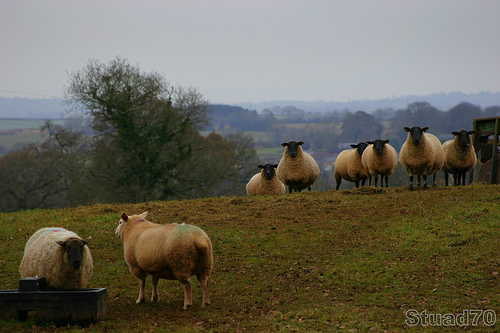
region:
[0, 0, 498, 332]
an outdoor scene of a herd of sheep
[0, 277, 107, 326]
a water trough for the sheep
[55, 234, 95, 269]
the black face of the sheep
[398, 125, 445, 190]
thick wool of the sheep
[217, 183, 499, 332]
a hilly field for sheep grazing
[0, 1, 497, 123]
grey hazy sky in the distance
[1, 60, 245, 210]
large trees on the other side of the hill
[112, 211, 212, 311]
this sheep has a white face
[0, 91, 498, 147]
hills and valleys in the distance behind the sheep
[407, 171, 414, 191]
skinny legs of the sheep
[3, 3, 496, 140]
The sky is grey.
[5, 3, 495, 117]
The sky is overcast.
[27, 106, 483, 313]
Sheep are grazing.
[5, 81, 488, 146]
Mountains in the background.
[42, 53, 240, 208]
The leaves are green.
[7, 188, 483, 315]
The grass is brown and green.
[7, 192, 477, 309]
The grass is patchy.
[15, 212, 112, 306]
Sheep laying down.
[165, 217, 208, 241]
Green marking on sheep.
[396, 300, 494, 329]
The text is white.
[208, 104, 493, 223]
sheep standing on a hill top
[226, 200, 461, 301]
ground is brown and green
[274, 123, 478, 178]
sheep have black faces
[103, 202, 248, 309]
sheep not facing camera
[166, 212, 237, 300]
sheep with green marking on back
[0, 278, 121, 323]
container of water for sheep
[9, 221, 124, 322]
sheep by water container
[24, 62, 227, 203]
nearby tree tops are visible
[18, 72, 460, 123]
lots of hills in the background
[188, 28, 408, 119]
sky is grey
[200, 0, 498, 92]
sky with white clouds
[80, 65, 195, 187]
a tree with green leaves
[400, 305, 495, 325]
Name of the photographer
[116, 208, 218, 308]
a white sheep in field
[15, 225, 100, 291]
a sheep covered in white wool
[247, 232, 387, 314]
a field with green grass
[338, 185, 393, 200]
a mound of green grass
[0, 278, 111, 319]
a sheep feeding bin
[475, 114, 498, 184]
a brown wooden sign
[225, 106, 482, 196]
a group of sheep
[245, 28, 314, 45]
hazy sky in the background.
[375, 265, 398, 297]
grass on the ground.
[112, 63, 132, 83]
bare branches on the trees.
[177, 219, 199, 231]
green patch on sheep's back.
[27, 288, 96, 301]
trough for the sheep.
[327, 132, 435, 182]
group of sheep on the hill.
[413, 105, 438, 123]
trees in the distance.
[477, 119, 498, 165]
wooden fence near the sheep.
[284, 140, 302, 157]
black head of sheep.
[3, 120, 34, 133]
pasture in the distance.